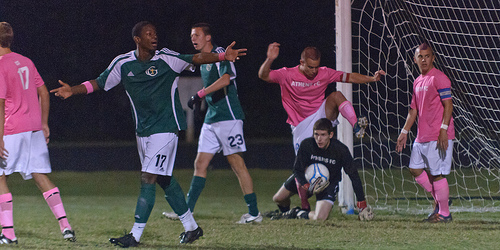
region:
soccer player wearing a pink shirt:
[0, 18, 80, 244]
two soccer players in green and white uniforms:
[46, 19, 260, 249]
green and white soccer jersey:
[94, 49, 199, 137]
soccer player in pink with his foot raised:
[258, 40, 390, 158]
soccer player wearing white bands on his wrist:
[389, 40, 460, 227]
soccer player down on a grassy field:
[263, 116, 377, 226]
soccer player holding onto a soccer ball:
[262, 115, 377, 224]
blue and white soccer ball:
[302, 162, 333, 192]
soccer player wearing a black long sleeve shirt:
[270, 118, 377, 223]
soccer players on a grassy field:
[0, 16, 459, 248]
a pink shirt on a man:
[408, 69, 458, 142]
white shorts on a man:
[406, 137, 457, 174]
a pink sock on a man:
[432, 174, 455, 215]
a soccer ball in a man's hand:
[304, 161, 332, 190]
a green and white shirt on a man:
[97, 48, 196, 136]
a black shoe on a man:
[175, 222, 205, 245]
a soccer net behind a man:
[334, 0, 499, 213]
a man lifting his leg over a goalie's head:
[261, 38, 389, 219]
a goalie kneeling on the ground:
[268, 115, 370, 225]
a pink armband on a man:
[80, 78, 98, 95]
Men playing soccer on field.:
[188, 19, 390, 227]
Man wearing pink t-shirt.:
[410, 69, 458, 143]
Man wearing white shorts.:
[403, 137, 459, 177]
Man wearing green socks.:
[185, 173, 260, 217]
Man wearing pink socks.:
[410, 170, 457, 219]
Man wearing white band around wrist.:
[437, 119, 455, 133]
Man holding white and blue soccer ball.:
[300, 162, 332, 197]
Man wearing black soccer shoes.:
[99, 224, 206, 248]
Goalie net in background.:
[337, 26, 499, 214]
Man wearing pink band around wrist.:
[76, 73, 99, 97]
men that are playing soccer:
[69, 21, 458, 243]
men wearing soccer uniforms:
[64, 44, 497, 214]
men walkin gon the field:
[30, 25, 499, 235]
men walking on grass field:
[54, 1, 416, 246]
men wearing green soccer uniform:
[101, 13, 289, 245]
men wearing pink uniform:
[265, 32, 492, 182]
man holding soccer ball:
[279, 87, 460, 244]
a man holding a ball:
[273, 97, 389, 239]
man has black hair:
[130, 18, 144, 33]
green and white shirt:
[82, 47, 187, 138]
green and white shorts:
[127, 126, 179, 181]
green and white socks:
[127, 179, 199, 239]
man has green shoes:
[115, 219, 205, 246]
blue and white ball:
[304, 154, 335, 186]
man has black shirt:
[292, 126, 349, 183]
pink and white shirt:
[408, 74, 462, 135]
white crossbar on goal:
[327, 12, 358, 211]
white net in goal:
[347, 12, 497, 219]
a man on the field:
[380, 45, 482, 195]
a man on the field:
[296, 118, 343, 226]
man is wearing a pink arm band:
[48, 20, 251, 249]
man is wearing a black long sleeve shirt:
[259, 116, 374, 223]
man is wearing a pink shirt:
[393, 38, 457, 224]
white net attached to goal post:
[336, 1, 498, 218]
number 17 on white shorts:
[136, 129, 177, 177]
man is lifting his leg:
[257, 41, 388, 212]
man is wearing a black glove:
[161, 21, 261, 226]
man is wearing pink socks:
[1, 21, 76, 246]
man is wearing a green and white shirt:
[49, 18, 246, 248]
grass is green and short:
[1, 168, 499, 247]